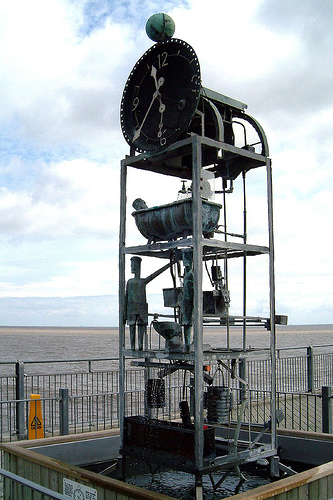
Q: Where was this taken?
A: Boardwalk next to the ocean.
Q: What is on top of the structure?
A: A clock.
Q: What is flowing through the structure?
A: Water.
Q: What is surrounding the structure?
A: A fence.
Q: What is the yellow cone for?
A: Caution wet floor.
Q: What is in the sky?
A: Clouds.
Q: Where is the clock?
A: On top of the tower.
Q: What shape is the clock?
A: Round.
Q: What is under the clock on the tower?
A: Bathtub.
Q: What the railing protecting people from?
A: Falling into the water.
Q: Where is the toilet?
A: Floor under the bathtub.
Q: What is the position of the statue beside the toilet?
A: Standing.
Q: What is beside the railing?
A: Yellow caution sign.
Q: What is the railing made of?
A: Metal.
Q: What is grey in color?
A: A tower.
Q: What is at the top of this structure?
A: A ball.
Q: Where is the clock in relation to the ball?
A: Under the ball.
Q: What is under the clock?
A: A statue of a bathtub.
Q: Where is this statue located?
A: On a beach.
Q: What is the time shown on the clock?
A: 11:30.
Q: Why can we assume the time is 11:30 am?
A: Because it is daytime.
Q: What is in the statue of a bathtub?
A: A person bathing.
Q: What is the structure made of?
A: Metal.